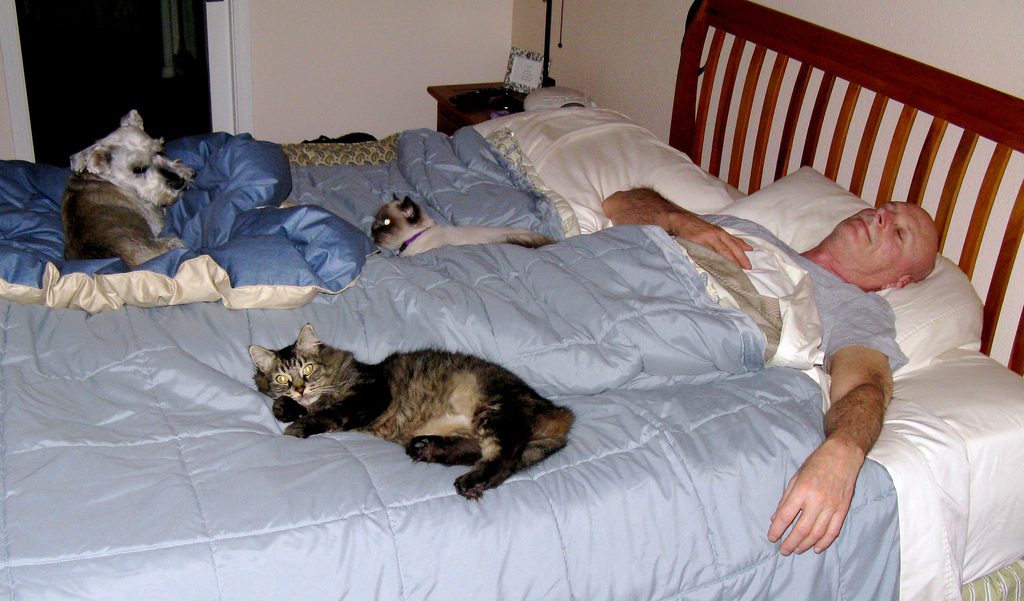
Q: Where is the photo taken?
A: The bedroom.